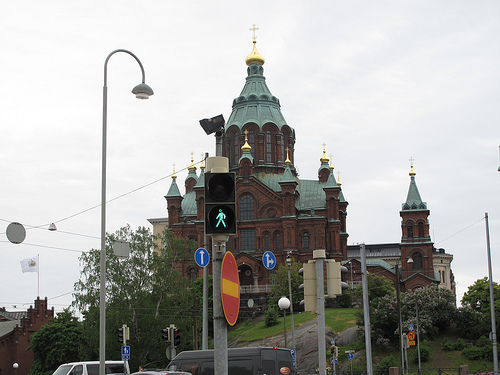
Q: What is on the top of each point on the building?
A: Crosses.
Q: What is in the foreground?
A: A tall light post.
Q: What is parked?
A: 2 vehicles.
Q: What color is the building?
A: Red.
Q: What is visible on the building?
A: 6 yellow tops.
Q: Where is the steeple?
A: On top of old church.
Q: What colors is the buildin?
A: Red, green, and tan.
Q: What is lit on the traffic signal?
A: Walk sign.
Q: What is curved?
A: The light pole.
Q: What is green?
A: Grass.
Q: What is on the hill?
A: The large building.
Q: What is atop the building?
A: A cross.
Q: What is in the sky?
A: Clouds.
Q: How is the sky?
A: Overcast.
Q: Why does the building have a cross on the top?
A: Its a church.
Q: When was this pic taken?
A: Daytime.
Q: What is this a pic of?
A: A church.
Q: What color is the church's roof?
A: Green.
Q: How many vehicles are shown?
A: Three.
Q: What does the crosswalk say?
A: It's safe to cross.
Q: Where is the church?
A: On a hill.